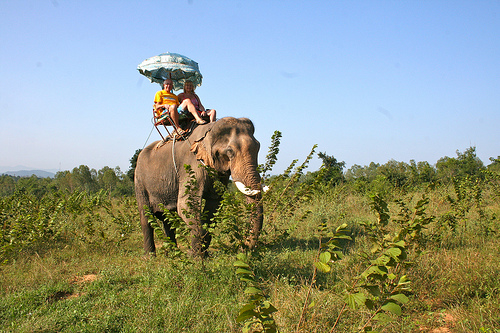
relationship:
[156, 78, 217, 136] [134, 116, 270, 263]
couple on elephant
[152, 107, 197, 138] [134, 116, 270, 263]
saddle on elephant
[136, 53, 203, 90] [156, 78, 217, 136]
umbrella over couple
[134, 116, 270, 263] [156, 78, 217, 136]
elephant with couple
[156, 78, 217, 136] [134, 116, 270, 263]
couple riding elephant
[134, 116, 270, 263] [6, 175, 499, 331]
elephant in field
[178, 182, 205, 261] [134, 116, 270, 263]
leg of elephant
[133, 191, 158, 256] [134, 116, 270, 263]
leg of elephant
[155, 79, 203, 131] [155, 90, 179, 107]
man wears shirt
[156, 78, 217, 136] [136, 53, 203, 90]
couple under umbrella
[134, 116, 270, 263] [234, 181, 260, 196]
elephant has tusk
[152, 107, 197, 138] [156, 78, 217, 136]
saddle for couple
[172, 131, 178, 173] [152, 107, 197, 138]
strap for saddle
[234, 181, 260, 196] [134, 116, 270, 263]
tusk of elephant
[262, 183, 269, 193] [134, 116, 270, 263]
tusk of elephant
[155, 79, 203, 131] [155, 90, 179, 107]
man in shirt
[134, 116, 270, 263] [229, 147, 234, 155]
elephant has eye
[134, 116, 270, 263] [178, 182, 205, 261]
elephant has leg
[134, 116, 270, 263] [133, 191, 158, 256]
elephant has leg